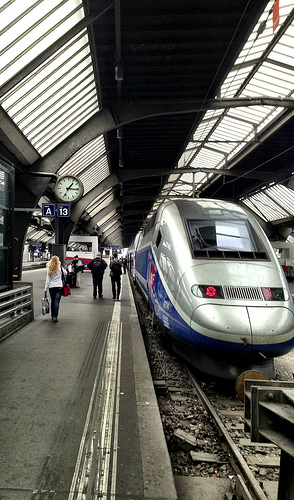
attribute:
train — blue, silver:
[122, 194, 292, 380]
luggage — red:
[36, 288, 49, 319]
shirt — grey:
[109, 257, 123, 276]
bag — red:
[62, 281, 72, 297]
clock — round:
[53, 174, 83, 203]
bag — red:
[60, 265, 72, 296]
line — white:
[97, 318, 133, 396]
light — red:
[205, 285, 215, 297]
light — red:
[261, 288, 270, 298]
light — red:
[203, 288, 216, 297]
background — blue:
[43, 201, 54, 217]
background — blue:
[57, 205, 70, 218]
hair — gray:
[94, 250, 102, 256]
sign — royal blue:
[41, 203, 54, 216]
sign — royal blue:
[57, 203, 70, 217]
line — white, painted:
[63, 300, 119, 497]